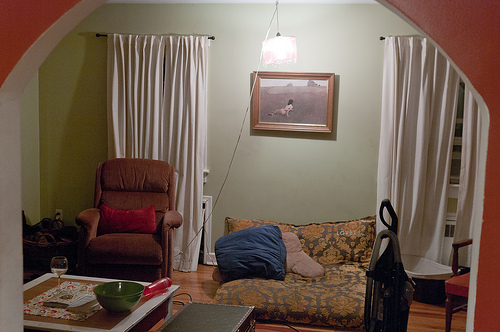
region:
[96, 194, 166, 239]
red throw pillow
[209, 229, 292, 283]
blue throw pillow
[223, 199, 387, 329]
beige and gold print on chair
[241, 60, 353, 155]
wooden framed artwork hung on wall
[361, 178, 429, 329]
vaccuum cleaner and hose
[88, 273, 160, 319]
green plastic bowl on table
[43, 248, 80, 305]
clear winde glass on table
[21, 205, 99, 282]
wicker basket in corner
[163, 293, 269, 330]
storage turnk in corner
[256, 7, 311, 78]
light hanging from ceiling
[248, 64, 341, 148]
Picture in a brown frame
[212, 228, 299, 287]
A blue pillow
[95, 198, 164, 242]
A dark red pillow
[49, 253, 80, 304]
A half full wine glass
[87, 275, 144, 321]
A green bowl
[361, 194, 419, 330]
An upright vaccume cleaner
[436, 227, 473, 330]
Part of a chair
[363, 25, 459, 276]
A white window curtain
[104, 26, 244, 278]
Closed white window curtains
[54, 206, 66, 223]
An electrical outlet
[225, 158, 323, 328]
A couch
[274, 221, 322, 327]
A couch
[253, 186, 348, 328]
A couch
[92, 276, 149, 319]
A big green bowl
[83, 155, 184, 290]
A brown reclining chair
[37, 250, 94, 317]
A wine glass on a table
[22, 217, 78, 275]
A big basket with two handles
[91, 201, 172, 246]
A red pillow in a chair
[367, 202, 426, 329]
An upright vacuum cleaner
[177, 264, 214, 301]
A hardwood floor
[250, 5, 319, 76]
A hanging light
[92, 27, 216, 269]
A pair of white curtains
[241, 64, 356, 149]
A framed picture hanging on the wall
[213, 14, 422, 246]
A picture frame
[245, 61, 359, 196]
A picture frame